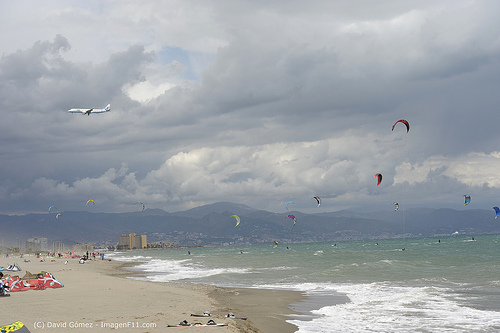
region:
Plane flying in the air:
[57, 100, 112, 120]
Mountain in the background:
[140, 181, 277, 238]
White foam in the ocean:
[319, 285, 446, 332]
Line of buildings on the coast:
[15, 234, 159, 250]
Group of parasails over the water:
[195, 131, 424, 228]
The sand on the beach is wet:
[95, 271, 160, 313]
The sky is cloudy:
[140, 22, 345, 110]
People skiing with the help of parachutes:
[372, 92, 449, 274]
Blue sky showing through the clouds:
[155, 38, 208, 84]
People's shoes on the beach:
[170, 310, 215, 332]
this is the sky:
[113, 48, 208, 70]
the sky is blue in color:
[165, 50, 184, 62]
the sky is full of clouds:
[241, 43, 355, 165]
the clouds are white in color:
[245, 33, 312, 99]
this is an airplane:
[63, 99, 115, 123]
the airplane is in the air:
[61, 99, 125, 121]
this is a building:
[120, 231, 153, 250]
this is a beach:
[118, 270, 492, 331]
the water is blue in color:
[298, 241, 312, 251]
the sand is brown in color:
[75, 285, 110, 311]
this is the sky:
[79, 24, 434, 199]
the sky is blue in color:
[13, 152, 45, 167]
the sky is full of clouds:
[119, 14, 482, 165]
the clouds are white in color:
[296, 25, 391, 102]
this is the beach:
[115, 261, 270, 296]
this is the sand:
[79, 284, 106, 314]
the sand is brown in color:
[79, 280, 114, 330]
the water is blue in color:
[407, 240, 481, 257]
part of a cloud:
[263, 52, 318, 90]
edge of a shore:
[241, 275, 271, 300]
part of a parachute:
[358, 160, 387, 192]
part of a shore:
[364, 265, 401, 312]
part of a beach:
[91, 282, 115, 304]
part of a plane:
[77, 98, 101, 140]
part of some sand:
[96, 290, 131, 325]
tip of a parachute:
[385, 115, 397, 142]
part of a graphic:
[130, 311, 158, 331]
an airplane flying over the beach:
[64, 97, 116, 119]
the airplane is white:
[66, 97, 111, 117]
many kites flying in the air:
[35, 114, 496, 251]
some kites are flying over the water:
[127, 107, 498, 254]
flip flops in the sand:
[167, 307, 247, 330]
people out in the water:
[179, 225, 493, 257]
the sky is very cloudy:
[0, 1, 497, 220]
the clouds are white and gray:
[7, 20, 490, 208]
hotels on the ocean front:
[27, 229, 164, 258]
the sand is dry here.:
[40, 286, 147, 331]